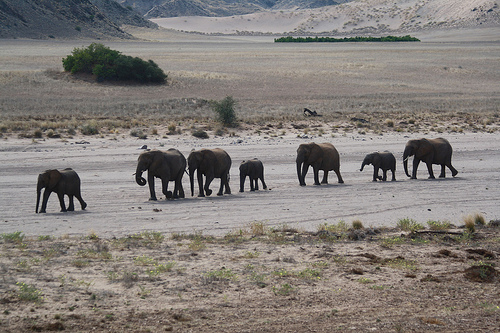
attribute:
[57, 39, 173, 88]
plants — green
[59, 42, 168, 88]
plants — green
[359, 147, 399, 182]
elephant — small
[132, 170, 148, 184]
trunk — curled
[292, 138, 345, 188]
elephant — large, walking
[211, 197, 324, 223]
ground — white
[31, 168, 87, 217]
elephant — leading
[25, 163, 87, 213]
elephant — walking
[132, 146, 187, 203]
elephant — walking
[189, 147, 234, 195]
elephant — walking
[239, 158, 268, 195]
elephant — walking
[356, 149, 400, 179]
elephant — walking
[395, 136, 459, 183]
elephant — walking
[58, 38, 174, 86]
bush — lush, green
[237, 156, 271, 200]
elephant —  smaller baby 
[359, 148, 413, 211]
elephant — smaller baby 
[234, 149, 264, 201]
elephant — smaller baby 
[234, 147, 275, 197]
elephant — smaller baby 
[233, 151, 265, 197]
elephant — smaller baby 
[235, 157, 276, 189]
elephant — smaller baby 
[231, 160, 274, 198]
elephant — smaller baby 